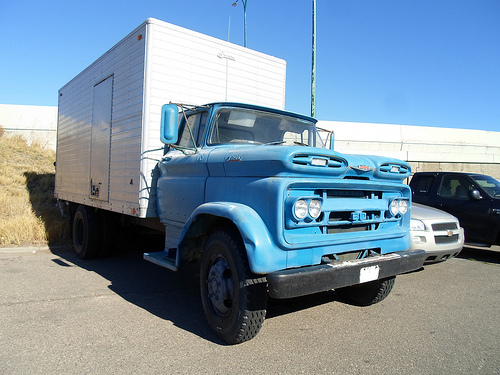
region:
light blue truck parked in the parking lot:
[54, 18, 426, 343]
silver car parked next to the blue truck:
[398, 201, 468, 264]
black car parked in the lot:
[411, 168, 499, 240]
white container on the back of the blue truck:
[51, 18, 287, 220]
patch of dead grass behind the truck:
[1, 129, 78, 250]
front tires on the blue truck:
[198, 252, 396, 344]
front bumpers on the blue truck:
[266, 248, 428, 304]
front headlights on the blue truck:
[291, 195, 408, 230]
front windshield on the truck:
[206, 112, 327, 147]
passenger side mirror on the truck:
[157, 98, 196, 155]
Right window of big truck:
[153, 95, 192, 154]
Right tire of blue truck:
[175, 209, 277, 355]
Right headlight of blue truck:
[290, 186, 328, 225]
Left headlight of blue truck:
[384, 193, 418, 224]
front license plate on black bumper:
[348, 260, 386, 289]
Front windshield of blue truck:
[205, 103, 325, 153]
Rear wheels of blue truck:
[56, 197, 123, 269]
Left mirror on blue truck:
[317, 125, 342, 155]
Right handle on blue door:
[156, 152, 177, 165]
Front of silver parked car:
[411, 195, 471, 273]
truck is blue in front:
[43, 12, 428, 346]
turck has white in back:
[42, 7, 429, 347]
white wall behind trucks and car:
[0, 97, 499, 347]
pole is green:
[307, 0, 317, 151]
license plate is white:
[356, 262, 381, 287]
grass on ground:
[0, 125, 82, 252]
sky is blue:
[1, 0, 498, 132]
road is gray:
[0, 235, 497, 371]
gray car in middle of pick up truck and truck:
[45, 16, 492, 349]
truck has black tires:
[48, 5, 428, 344]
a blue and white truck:
[46, 1, 418, 371]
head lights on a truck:
[292, 196, 408, 223]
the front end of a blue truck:
[284, 184, 415, 249]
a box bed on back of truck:
[53, 29, 281, 205]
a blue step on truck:
[137, 236, 187, 273]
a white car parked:
[411, 200, 468, 262]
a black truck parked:
[407, 173, 498, 270]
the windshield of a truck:
[207, 114, 320, 149]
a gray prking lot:
[3, 261, 118, 371]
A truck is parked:
[51, 17, 423, 344]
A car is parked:
[408, 201, 463, 263]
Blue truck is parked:
[408, 171, 498, 251]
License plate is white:
[360, 264, 379, 281]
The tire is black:
[194, 236, 264, 346]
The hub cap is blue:
[206, 260, 232, 311]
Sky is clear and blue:
[0, 0, 497, 130]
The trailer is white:
[54, 19, 286, 216]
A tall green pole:
[309, 0, 315, 117]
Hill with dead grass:
[2, 129, 70, 244]